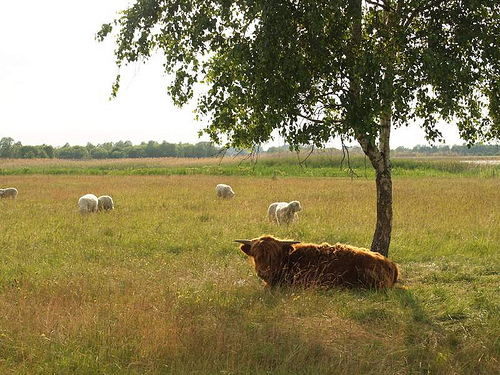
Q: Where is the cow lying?
A: On ground.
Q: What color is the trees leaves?
A: Green.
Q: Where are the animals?
A: Grass field.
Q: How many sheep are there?
A: 5.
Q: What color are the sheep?
A: White.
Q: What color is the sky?
A: White.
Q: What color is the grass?
A: Green.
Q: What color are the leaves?
A: Green.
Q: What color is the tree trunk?
A: Brown.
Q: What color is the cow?
A: Brown.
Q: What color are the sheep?
A: White.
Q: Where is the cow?
A: Under the tree.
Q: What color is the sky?
A: White.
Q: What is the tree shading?
A: The cow.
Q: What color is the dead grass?
A: Brown.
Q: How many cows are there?
A: One.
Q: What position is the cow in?
A: Laying on the ground.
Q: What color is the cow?
A: Brown.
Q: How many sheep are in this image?
A: 4.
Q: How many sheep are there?
A: 5.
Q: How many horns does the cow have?
A: 2.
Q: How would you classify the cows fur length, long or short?
A: Long.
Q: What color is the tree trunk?
A: Grey and white.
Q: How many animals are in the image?
A: 6.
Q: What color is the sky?
A: White.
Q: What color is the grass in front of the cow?
A: Green and brown.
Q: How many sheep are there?
A: Five.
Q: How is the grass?
A: Tall.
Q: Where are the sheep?
A: In a pasture.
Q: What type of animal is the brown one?
A: A steer.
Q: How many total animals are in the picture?
A: Six.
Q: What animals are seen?
A: Bull and sheep.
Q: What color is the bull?
A: Brown.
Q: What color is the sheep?
A: White.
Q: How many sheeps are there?
A: 5.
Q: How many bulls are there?
A: 1.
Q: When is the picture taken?
A: Daytime.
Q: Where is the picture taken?
A: In a grassland.